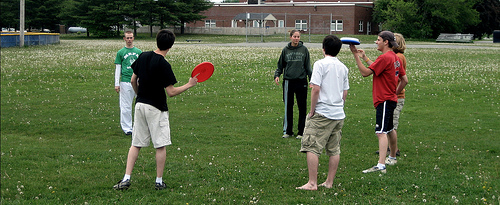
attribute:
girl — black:
[274, 29, 309, 132]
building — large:
[181, 0, 382, 41]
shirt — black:
[107, 47, 184, 109]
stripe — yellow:
[3, 28, 53, 37]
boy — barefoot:
[288, 33, 353, 194]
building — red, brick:
[182, 2, 375, 33]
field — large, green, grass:
[4, 37, 497, 204]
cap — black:
[374, 26, 401, 46]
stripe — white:
[282, 80, 292, 137]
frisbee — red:
[186, 58, 223, 96]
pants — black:
[278, 78, 312, 135]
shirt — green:
[113, 45, 145, 77]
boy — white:
[350, 31, 391, 176]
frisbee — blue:
[341, 31, 361, 49]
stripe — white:
[378, 99, 386, 134]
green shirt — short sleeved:
[114, 45, 140, 82]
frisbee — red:
[191, 59, 215, 85]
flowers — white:
[25, 34, 498, 81]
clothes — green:
[287, 44, 304, 136]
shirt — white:
[318, 58, 345, 113]